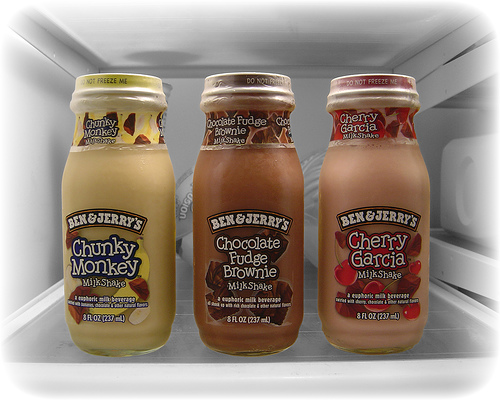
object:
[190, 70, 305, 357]
bottle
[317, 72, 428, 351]
bottle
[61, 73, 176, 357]
bottle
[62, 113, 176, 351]
milkshake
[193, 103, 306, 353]
milkshake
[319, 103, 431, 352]
milkshake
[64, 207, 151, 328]
label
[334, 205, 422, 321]
label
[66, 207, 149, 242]
brand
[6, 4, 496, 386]
cooler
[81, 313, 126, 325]
size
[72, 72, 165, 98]
lid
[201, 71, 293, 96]
lid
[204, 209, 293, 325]
label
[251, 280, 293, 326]
brownie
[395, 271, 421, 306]
chocolate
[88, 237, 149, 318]
banana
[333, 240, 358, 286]
cherry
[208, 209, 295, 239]
brand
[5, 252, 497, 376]
shelf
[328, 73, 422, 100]
lid